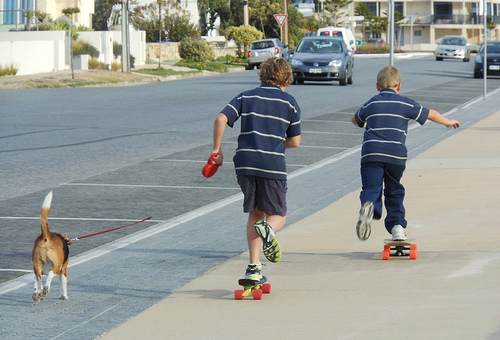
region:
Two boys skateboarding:
[205, 54, 460, 302]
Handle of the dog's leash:
[199, 151, 224, 181]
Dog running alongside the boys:
[25, 188, 75, 307]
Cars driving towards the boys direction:
[286, 34, 471, 88]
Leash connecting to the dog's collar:
[70, 153, 222, 244]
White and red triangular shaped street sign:
[272, 10, 287, 30]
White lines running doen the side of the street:
[0, 92, 490, 306]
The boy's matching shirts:
[218, 81, 432, 181]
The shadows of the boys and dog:
[2, 238, 385, 303]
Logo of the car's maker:
[309, 61, 321, 68]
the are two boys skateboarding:
[189, 44, 450, 302]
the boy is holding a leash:
[20, 52, 329, 312]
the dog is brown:
[19, 172, 122, 335]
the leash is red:
[175, 138, 245, 218]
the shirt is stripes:
[215, 70, 305, 204]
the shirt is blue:
[357, 88, 452, 174]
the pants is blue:
[342, 141, 411, 213]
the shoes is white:
[346, 198, 420, 247]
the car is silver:
[282, 16, 377, 102]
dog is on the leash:
[23, 178, 118, 318]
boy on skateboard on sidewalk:
[197, 47, 306, 314]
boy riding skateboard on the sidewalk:
[337, 48, 465, 278]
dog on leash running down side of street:
[0, 142, 234, 316]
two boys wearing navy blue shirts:
[201, 47, 437, 240]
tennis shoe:
[246, 215, 283, 270]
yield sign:
[270, 10, 297, 55]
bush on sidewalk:
[170, 30, 229, 87]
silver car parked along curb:
[205, 22, 297, 84]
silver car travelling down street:
[405, 23, 493, 81]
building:
[308, 0, 497, 59]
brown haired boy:
[203, 53, 314, 303]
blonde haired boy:
[355, 61, 443, 265]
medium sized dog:
[24, 184, 96, 309]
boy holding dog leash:
[7, 54, 297, 306]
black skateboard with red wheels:
[223, 248, 285, 304]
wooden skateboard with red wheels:
[374, 230, 433, 266]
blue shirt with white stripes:
[219, 81, 308, 183]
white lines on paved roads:
[63, 161, 236, 253]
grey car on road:
[288, 38, 370, 88]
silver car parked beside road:
[244, 39, 290, 71]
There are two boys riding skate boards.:
[193, 27, 498, 184]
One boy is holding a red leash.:
[62, 169, 227, 238]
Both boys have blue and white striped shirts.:
[222, 71, 454, 190]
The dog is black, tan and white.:
[8, 173, 103, 304]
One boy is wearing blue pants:
[337, 161, 422, 226]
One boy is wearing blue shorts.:
[235, 175, 295, 216]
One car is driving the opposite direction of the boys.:
[284, 24, 355, 91]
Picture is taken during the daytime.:
[4, 13, 497, 206]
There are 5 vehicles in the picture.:
[234, 15, 498, 75]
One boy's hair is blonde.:
[362, 65, 409, 96]